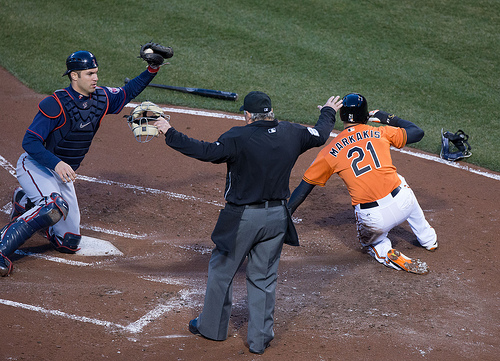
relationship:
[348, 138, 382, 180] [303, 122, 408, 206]
number 21 on jersey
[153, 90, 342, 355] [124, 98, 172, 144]
man face facemask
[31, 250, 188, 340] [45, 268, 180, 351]
markings of floor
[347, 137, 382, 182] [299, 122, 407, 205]
black numbers on shirt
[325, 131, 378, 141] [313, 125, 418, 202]
letters on shirt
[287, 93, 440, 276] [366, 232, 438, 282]
baseball runner wears shoe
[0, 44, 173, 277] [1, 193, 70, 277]
cather wears leg pad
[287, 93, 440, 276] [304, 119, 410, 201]
baseball runner wears jersey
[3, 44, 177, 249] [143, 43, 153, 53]
cather holds ball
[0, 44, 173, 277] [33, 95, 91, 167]
cather has uniform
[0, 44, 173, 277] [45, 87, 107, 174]
cather wearing nike vest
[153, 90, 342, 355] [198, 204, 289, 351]
man has pants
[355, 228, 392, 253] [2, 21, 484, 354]
man's knee on ground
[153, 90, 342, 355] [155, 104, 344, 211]
man wears shirt